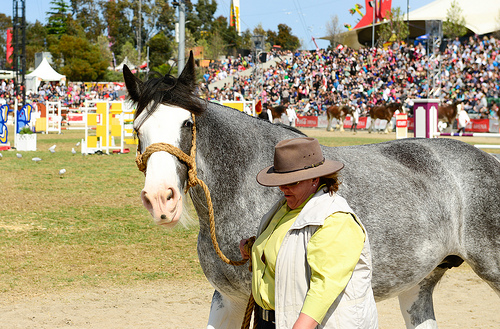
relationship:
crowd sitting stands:
[0, 34, 500, 120] [295, 52, 439, 107]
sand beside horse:
[97, 287, 191, 318] [115, 57, 472, 327]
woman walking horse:
[232, 128, 372, 327] [116, 47, 498, 327]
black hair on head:
[120, 49, 197, 110] [117, 60, 207, 227]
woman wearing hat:
[232, 128, 372, 327] [252, 134, 346, 189]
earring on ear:
[311, 182, 316, 189] [311, 176, 320, 187]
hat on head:
[255, 136, 343, 186] [278, 175, 327, 205]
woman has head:
[232, 128, 372, 327] [278, 175, 327, 205]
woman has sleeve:
[232, 128, 372, 327] [299, 212, 361, 322]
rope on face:
[138, 145, 186, 162] [135, 100, 206, 222]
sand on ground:
[97, 296, 191, 317] [2, 127, 498, 327]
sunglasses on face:
[275, 176, 302, 193] [277, 182, 306, 208]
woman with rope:
[232, 128, 372, 327] [144, 141, 194, 184]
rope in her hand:
[144, 141, 194, 184] [231, 239, 252, 264]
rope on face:
[137, 120, 237, 275] [135, 91, 197, 219]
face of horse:
[135, 91, 197, 219] [116, 47, 498, 327]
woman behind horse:
[232, 128, 372, 327] [116, 47, 498, 327]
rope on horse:
[137, 120, 237, 275] [116, 47, 498, 327]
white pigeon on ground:
[58, 167, 68, 173] [1, 146, 207, 286]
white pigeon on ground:
[28, 155, 43, 160] [1, 146, 207, 286]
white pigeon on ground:
[15, 152, 24, 158] [1, 146, 207, 286]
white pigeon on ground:
[68, 144, 78, 155] [1, 146, 207, 286]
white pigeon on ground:
[48, 142, 57, 153] [1, 146, 207, 286]